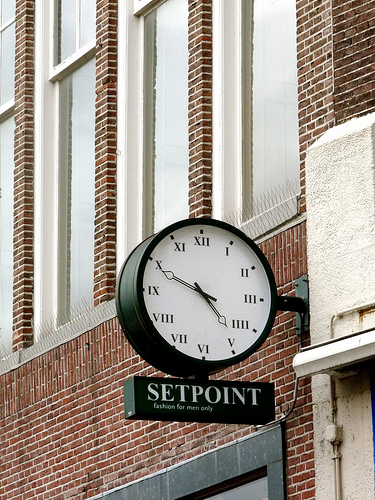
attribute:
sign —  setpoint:
[133, 381, 274, 414]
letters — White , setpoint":
[145, 381, 264, 409]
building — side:
[15, 3, 370, 216]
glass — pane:
[200, 462, 282, 497]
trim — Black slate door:
[81, 422, 286, 498]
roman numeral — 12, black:
[197, 232, 208, 251]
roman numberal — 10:
[193, 236, 210, 246]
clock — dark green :
[115, 216, 312, 378]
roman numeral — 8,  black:
[150, 310, 175, 325]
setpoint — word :
[142, 379, 260, 409]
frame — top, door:
[290, 325, 369, 374]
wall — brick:
[0, 219, 312, 497]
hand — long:
[162, 270, 217, 301]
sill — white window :
[32, 307, 95, 354]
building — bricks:
[3, 6, 363, 498]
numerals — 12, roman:
[189, 234, 214, 254]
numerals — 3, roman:
[241, 291, 262, 304]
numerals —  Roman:
[149, 238, 258, 351]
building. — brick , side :
[3, 2, 363, 493]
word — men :
[136, 373, 260, 409]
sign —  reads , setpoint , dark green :
[120, 374, 276, 427]